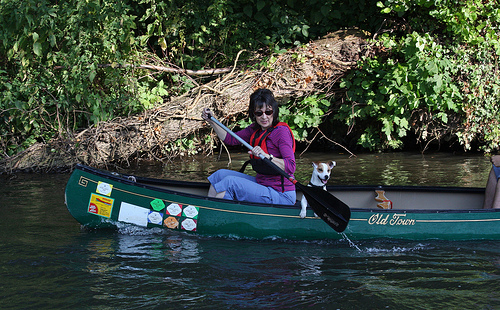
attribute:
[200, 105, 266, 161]
handle — metal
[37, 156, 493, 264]
canoe — green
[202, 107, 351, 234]
paddle — black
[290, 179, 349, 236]
black oar — silver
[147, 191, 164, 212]
sticker — green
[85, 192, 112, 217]
sticker — yellow, red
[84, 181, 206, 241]
stickers — multi-colored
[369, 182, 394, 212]
seat — brown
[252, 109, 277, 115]
sunglasses — dark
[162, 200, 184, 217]
sticker — white, red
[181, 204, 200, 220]
sticker — white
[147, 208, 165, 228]
sticker — blue, white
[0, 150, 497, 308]
river — flat, dark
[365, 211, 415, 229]
old town — gold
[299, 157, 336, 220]
dog — panting, white